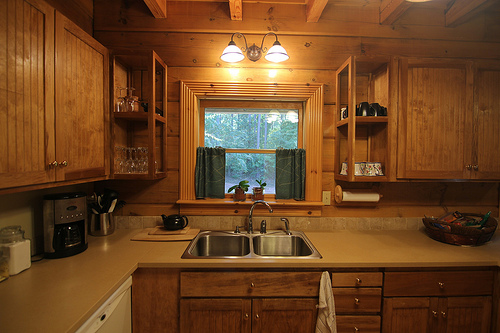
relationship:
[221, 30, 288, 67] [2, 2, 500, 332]
lights are in kitchen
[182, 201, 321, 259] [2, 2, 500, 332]
sink in kitchen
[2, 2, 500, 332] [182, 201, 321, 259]
kitchen has a sink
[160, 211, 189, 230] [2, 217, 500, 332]
teapot on counter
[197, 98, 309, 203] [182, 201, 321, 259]
window above sink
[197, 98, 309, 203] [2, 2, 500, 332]
window in kitchen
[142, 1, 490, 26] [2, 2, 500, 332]
beams in kitchen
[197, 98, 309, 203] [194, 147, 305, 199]
window has curtains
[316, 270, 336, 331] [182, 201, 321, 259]
towel under sink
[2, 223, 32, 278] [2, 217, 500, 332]
jar on counter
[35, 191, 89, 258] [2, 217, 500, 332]
coffee maker on counter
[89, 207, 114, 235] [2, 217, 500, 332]
container on counter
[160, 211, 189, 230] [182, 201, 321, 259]
teapot left of sink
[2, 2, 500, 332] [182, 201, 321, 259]
kitchen has a double sink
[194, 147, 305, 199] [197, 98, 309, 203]
curtains are on bottom of window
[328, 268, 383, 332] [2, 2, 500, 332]
row of drawers are in kitchen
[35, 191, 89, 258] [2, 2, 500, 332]
coffee maker in kitchen